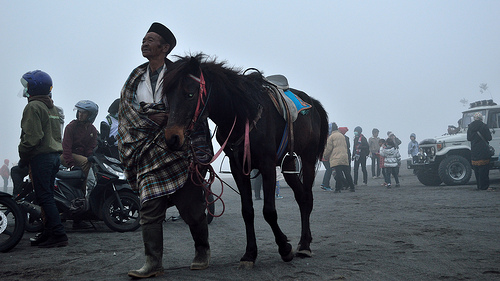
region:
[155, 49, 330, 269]
a black good looking horse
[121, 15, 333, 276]
a man with a horse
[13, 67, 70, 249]
a man wearing a helmet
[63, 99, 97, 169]
a man wearing a helmet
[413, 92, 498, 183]
a white truck parked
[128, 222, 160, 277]
a black boot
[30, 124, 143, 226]
a motorcycle parked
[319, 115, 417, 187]
some people standing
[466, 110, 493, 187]
a person wearing a hat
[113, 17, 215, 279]
a person wearing a hat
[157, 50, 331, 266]
a small brown horse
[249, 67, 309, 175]
a saddle on the horse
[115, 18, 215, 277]
a man wrapped in a plaid blanket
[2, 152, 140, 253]
two motercycles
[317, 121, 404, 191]
a group of people on a beach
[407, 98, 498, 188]
a white truck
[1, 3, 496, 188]
a misty day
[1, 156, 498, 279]
a sandy beach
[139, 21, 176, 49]
a black hat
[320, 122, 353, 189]
a person in a white coat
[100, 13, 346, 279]
A MAN WALKING WITH A HORSE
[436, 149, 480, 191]
A BLACK TRUCK TIRE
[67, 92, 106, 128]
A PROTECTIVE HELMUT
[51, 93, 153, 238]
A MAN SITTING ON A MOTORCYCLE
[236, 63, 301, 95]
A HORSE SADDLE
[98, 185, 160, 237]
A FRONT MOTORCYCLE WHEEL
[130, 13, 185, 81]
A MAN WEARING A BLACK HAT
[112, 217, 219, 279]
A PAIR OF BOOTS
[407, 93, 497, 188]
A WHITE TRUCK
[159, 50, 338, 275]
A BROWN HORSE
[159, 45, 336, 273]
The horse led by the man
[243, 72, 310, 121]
The saddle on the horse's back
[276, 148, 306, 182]
The stirrup on the horse's saddle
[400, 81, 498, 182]
The jeep in the background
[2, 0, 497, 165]
The gray sky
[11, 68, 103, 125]
The people's helmets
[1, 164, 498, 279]
The sand the people are on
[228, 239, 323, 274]
The horse's hooves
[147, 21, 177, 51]
The hat of the man leading the horse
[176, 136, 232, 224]
The rope connected to the horse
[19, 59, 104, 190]
two people wearing motorcycle helmets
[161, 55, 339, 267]
a dark brown horse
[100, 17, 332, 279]
a man walking a horse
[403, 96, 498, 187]
front end of a white jeep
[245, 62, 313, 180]
a leather saddle on the horse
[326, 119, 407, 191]
a group of people wearing jackets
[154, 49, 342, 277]
a horse walking on the sand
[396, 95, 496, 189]
a parked vehicle on the sand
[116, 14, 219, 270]
a man keeping warm with a blanket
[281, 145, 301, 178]
a silver strap on the saddle to put your foot